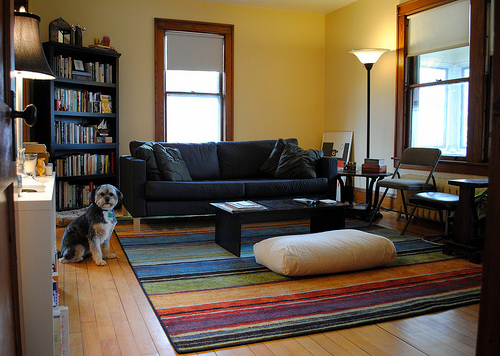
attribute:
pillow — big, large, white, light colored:
[252, 229, 395, 276]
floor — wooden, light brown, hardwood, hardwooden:
[56, 206, 485, 355]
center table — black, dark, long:
[212, 201, 348, 256]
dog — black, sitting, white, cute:
[61, 185, 124, 268]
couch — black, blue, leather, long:
[119, 138, 335, 225]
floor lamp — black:
[352, 49, 394, 223]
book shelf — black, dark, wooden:
[30, 42, 120, 210]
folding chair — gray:
[374, 149, 441, 233]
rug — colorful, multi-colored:
[114, 217, 483, 352]